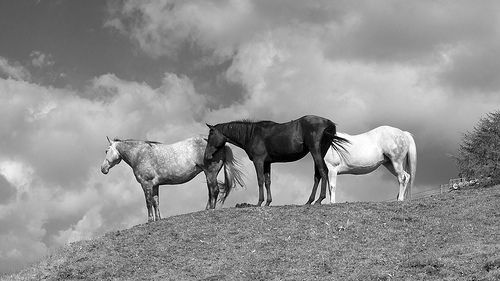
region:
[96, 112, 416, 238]
Three horses standing together on a hill.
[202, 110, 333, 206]
A black horse on the hill.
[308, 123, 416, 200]
A white horse next to the black horse.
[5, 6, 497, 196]
A cloudy sky.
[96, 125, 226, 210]
A light colored horse with a patchy coat.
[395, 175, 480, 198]
The edge of a fence.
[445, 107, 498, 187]
the edge of a shrub.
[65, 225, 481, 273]
The hill has a grassy terrian.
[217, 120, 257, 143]
The black horse has a black main.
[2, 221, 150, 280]
A downward slop on the hill.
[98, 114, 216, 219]
the horse is grey and white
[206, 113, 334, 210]
the horse is black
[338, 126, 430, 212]
the horse is white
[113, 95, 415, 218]
the horses are on a hill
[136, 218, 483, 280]
the hill is grassy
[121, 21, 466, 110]
the sky is cloudy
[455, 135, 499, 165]
a tree is in the background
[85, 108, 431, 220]
the horses are outside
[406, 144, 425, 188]
the tail is white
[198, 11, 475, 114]
the clouds have rain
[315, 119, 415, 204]
Body of a white horse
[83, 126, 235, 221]
Speckled horse standing on a hill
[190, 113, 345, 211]
Black horse standing on a hill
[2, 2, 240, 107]
Patch of sky in the clouds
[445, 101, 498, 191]
Tree on top of the hill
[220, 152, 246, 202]
Horse's tail blowing in the wind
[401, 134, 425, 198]
White horse tail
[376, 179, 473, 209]
Fence on the back of the hill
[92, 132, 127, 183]
White horse's head pointed away from the camera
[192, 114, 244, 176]
Black horse head pointed away from the camera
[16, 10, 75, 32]
this is the sky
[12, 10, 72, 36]
the sky is clear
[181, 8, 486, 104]
the sky has some clouds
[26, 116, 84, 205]
the clouds are white in color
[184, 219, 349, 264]
this is the ground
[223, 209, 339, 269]
the ground has some grass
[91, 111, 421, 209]
these are three horses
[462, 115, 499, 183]
this is a tree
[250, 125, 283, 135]
the horse is black in color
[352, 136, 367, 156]
the fur is white in color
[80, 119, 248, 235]
Large horse standing on hillside.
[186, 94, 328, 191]
Large horse standing on hillside.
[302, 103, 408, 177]
Large horse standing on hillside.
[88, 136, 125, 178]
Horse has white head.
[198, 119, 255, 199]
Horse has dark head.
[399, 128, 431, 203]
Horse has white tail.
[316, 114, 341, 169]
Horse has dark tail.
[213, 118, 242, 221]
Horse has light tail.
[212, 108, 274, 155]
Horse has dark mane.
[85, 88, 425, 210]
3 horses standing by each other.